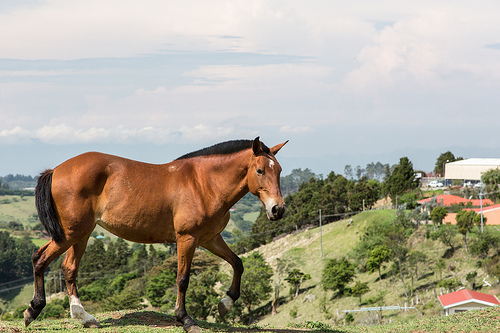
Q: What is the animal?
A: This is a horse.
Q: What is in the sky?
A: White clouds in blue sky.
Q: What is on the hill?
A: A horse on a hill.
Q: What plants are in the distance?
A: Trees in the distance.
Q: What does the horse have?
A: A black tail and mane.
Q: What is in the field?
A: A brown stallion in the field.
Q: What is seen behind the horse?
A: A cloudy sky.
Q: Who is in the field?
A: A brown horse.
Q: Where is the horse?
A: On a hilltop.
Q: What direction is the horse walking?
A: Towards the right.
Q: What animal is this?
A: Horse.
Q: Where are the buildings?
A: On the right side in the background.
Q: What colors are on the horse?
A: Brown, black, and white.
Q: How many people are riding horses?
A: Zero.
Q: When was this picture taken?
A: During the daytime.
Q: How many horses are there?
A: One.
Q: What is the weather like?
A: Bright and sunny.